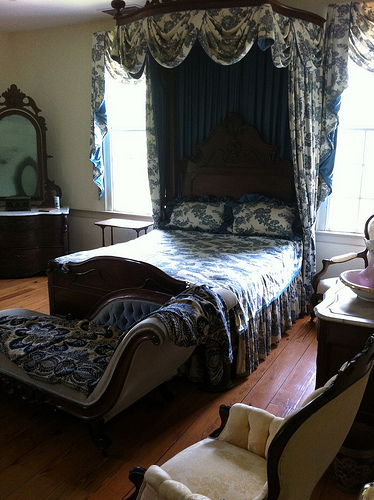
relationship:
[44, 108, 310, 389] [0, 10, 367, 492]
bed in bedroom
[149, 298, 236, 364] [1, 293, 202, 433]
blanket on chaise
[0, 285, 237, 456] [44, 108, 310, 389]
chair on bed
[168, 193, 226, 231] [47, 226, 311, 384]
pillow on bed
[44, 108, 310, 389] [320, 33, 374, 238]
bed in window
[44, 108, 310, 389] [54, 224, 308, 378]
bed with cover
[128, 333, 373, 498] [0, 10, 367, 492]
chair in a bedroom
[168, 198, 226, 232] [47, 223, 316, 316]
pillow on a bed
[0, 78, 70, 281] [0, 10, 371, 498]
vanity at corner of a bedroom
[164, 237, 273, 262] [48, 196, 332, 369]
fabric on top of bed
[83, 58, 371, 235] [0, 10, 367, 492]
window in a bedroom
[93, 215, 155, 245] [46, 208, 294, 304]
side table on a side of bed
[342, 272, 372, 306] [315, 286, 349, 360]
bowl on a side of table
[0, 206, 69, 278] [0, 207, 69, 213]
dresser has white counter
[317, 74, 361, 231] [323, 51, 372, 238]
sunlight coming window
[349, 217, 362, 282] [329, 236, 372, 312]
pitcher in bowl